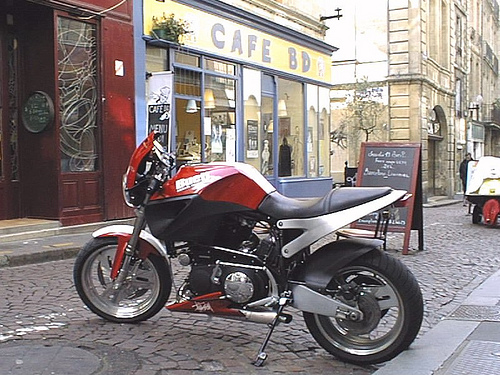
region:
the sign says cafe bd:
[202, 25, 322, 78]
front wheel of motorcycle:
[75, 230, 166, 322]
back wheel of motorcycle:
[300, 254, 410, 364]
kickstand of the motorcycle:
[249, 307, 283, 371]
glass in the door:
[35, 10, 95, 175]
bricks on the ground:
[110, 328, 188, 363]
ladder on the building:
[361, 0, 473, 140]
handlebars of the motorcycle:
[137, 92, 183, 187]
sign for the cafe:
[188, 20, 327, 81]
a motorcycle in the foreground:
[73, 137, 421, 370]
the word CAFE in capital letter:
[208, 22, 270, 63]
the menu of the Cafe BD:
[361, 147, 416, 234]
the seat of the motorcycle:
[263, 181, 389, 215]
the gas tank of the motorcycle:
[183, 161, 268, 209]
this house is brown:
[23, 4, 125, 224]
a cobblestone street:
[8, 268, 63, 325]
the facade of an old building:
[416, 0, 496, 175]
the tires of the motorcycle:
[71, 237, 424, 361]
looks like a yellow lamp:
[203, 89, 216, 110]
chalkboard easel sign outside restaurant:
[350, 138, 427, 244]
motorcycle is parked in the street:
[56, 135, 426, 358]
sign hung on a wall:
[14, 82, 65, 135]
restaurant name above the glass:
[201, 15, 315, 75]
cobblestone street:
[423, 234, 467, 305]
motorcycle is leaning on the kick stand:
[246, 313, 306, 374]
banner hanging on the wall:
[140, 65, 175, 159]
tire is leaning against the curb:
[386, 334, 415, 370]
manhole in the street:
[16, 319, 104, 371]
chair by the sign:
[356, 205, 401, 245]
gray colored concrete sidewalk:
[2, 208, 149, 266]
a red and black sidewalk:
[71, 131, 423, 366]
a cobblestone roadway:
[3, 198, 498, 372]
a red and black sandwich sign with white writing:
[347, 140, 422, 247]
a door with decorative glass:
[58, 14, 99, 221]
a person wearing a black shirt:
[458, 151, 473, 215]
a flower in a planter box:
[149, 13, 188, 43]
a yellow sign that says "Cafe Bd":
[141, 0, 333, 86]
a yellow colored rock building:
[328, 0, 458, 180]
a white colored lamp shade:
[186, 95, 198, 117]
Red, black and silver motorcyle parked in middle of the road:
[71, 130, 425, 368]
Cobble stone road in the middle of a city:
[0, 198, 499, 373]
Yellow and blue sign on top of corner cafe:
[144, 0, 329, 84]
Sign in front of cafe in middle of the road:
[350, 139, 425, 256]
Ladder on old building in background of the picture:
[381, 1, 413, 145]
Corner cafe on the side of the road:
[137, 0, 338, 200]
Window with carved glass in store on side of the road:
[57, 17, 97, 170]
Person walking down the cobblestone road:
[458, 152, 473, 197]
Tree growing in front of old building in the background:
[342, 76, 384, 142]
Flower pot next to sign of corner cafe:
[149, 13, 191, 44]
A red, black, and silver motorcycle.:
[74, 122, 426, 370]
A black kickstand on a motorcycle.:
[249, 300, 296, 372]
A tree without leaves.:
[329, 72, 398, 189]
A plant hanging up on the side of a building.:
[151, 9, 194, 49]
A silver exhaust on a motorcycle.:
[172, 275, 294, 330]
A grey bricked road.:
[6, 198, 498, 373]